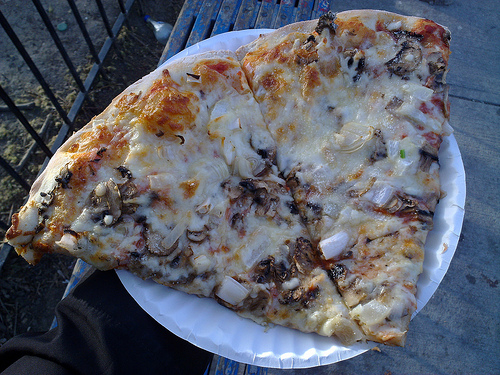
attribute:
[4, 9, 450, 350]
pizza — triangular, slices, sliced, delicious, bigger, cheesy, large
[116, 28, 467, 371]
plate — white, held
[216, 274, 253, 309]
onion — piece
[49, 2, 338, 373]
bench — blue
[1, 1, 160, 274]
railing — metal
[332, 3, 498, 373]
floor — cemented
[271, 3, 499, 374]
sidewalk — gray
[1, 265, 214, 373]
arm — black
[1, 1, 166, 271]
fence — metal, black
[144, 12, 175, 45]
bottle — plastic